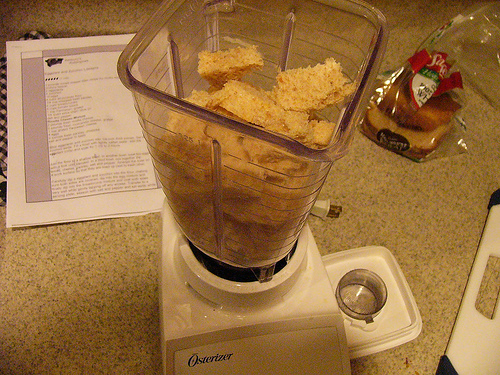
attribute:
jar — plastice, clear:
[115, 0, 387, 286]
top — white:
[324, 247, 423, 361]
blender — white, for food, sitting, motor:
[157, 196, 353, 373]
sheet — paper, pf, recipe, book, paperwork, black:
[4, 35, 156, 232]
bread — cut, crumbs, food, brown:
[152, 50, 354, 268]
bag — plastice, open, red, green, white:
[361, 0, 498, 162]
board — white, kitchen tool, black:
[437, 187, 500, 373]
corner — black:
[487, 186, 499, 210]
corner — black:
[432, 356, 457, 374]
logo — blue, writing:
[188, 353, 234, 368]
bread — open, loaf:
[360, 62, 461, 161]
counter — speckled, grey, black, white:
[2, 0, 499, 374]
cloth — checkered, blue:
[0, 32, 53, 203]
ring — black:
[184, 240, 306, 280]